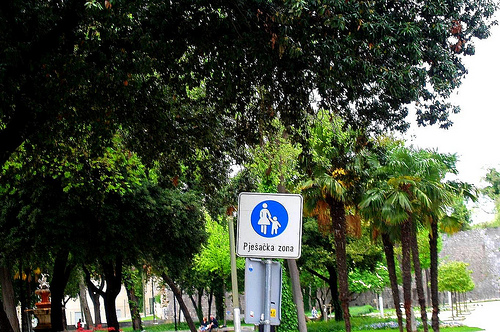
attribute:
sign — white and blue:
[238, 187, 305, 262]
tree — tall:
[414, 146, 473, 330]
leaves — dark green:
[0, 9, 490, 240]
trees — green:
[2, 15, 492, 329]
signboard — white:
[233, 187, 304, 261]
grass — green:
[81, 304, 489, 330]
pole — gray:
[249, 257, 290, 329]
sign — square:
[232, 182, 309, 262]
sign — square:
[235, 190, 302, 259]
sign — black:
[235, 189, 302, 267]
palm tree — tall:
[420, 159, 472, 329]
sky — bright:
[409, 1, 499, 177]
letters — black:
[239, 237, 293, 257]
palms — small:
[292, 122, 452, 329]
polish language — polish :
[239, 242, 296, 256]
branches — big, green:
[2, 4, 499, 331]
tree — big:
[11, 4, 182, 201]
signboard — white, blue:
[219, 183, 374, 290]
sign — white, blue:
[206, 185, 346, 266]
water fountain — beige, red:
[23, 284, 54, 331]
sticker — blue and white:
[245, 263, 254, 274]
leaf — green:
[353, 42, 359, 49]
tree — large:
[0, 0, 499, 167]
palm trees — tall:
[94, 37, 376, 219]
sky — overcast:
[225, 5, 497, 226]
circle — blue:
[249, 189, 288, 255]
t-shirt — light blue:
[308, 309, 317, 314]